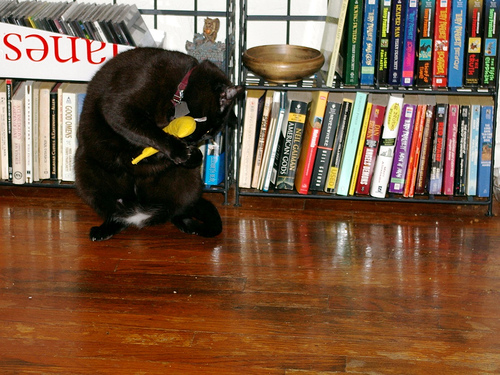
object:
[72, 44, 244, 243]
cat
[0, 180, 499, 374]
floor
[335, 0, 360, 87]
book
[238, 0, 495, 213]
shelf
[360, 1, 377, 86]
book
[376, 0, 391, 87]
book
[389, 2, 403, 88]
book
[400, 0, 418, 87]
book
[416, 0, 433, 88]
book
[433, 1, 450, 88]
book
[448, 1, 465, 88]
book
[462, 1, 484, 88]
book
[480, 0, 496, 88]
book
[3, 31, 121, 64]
lettering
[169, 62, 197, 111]
collar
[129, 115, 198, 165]
toy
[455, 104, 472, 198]
books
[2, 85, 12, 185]
books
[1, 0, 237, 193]
shelf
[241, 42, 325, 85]
dish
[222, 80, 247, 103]
ear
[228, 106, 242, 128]
ear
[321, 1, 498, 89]
books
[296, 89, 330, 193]
book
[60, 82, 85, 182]
good omens book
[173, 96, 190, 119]
tag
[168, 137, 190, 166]
paw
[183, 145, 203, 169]
paw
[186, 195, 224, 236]
tail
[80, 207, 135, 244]
legs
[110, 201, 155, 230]
patch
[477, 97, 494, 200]
book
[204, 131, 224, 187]
book